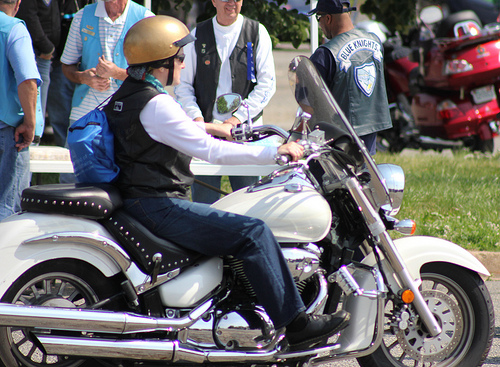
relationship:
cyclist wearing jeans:
[107, 14, 350, 349] [124, 196, 309, 330]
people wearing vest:
[173, 0, 275, 205] [182, 15, 262, 131]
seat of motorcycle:
[0, 151, 238, 283] [0, 51, 487, 334]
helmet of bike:
[113, 0, 205, 96] [0, 55, 495, 367]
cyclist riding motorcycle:
[107, 14, 350, 349] [0, 50, 496, 364]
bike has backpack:
[0, 55, 495, 367] [67, 88, 154, 183]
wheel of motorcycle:
[0, 215, 163, 364] [0, 50, 496, 364]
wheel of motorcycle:
[344, 231, 489, 363] [0, 50, 496, 364]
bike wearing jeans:
[0, 55, 495, 367] [104, 175, 318, 335]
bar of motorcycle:
[244, 93, 351, 200] [0, 50, 496, 364]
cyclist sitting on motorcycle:
[107, 14, 350, 349] [0, 50, 496, 364]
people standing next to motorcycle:
[1, 4, 435, 222] [0, 50, 496, 364]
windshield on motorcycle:
[282, 44, 403, 200] [0, 50, 496, 364]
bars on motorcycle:
[266, 100, 364, 181] [0, 50, 496, 364]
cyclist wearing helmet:
[107, 14, 350, 349] [113, 2, 216, 83]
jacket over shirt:
[101, 75, 196, 200] [134, 92, 280, 168]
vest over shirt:
[99, 73, 198, 193] [140, 91, 283, 172]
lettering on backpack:
[69, 150, 99, 179] [68, 103, 122, 189]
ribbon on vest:
[245, 33, 259, 83] [191, 10, 261, 121]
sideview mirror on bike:
[218, 83, 252, 133] [1, 54, 491, 364]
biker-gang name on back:
[332, 37, 379, 63] [333, 29, 386, 112]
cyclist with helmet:
[87, 8, 338, 364] [107, 6, 229, 93]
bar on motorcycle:
[233, 124, 291, 144] [6, 102, 482, 333]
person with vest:
[73, 5, 154, 166] [42, 1, 141, 147]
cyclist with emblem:
[107, 14, 350, 349] [97, 87, 136, 134]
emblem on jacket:
[97, 87, 136, 134] [88, 59, 226, 230]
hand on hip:
[12, 110, 54, 149] [4, 117, 40, 196]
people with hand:
[1, 0, 46, 222] [12, 110, 54, 149]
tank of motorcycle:
[218, 168, 355, 258] [10, 59, 483, 320]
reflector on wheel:
[390, 273, 427, 318] [349, 220, 485, 358]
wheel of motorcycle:
[349, 220, 485, 358] [0, 67, 454, 363]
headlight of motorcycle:
[362, 152, 426, 221] [19, 85, 420, 363]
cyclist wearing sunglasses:
[107, 14, 350, 349] [160, 37, 202, 80]